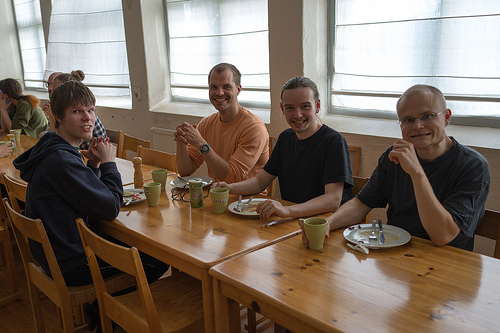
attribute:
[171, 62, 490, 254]
people — sitted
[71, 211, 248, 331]
chair — wooden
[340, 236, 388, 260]
napkin — paper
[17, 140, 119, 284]
jumper — blue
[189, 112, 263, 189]
shirt — orange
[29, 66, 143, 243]
woman — sitted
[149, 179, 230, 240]
shaker — light brown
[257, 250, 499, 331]
wooden table — rectangular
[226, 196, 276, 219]
plate — circular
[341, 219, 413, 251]
plate — white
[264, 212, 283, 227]
knife — silver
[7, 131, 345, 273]
table — rectangular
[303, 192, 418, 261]
plate — circular, white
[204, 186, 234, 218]
cup — brown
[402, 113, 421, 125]
lens — glasses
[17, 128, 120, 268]
jacket — blue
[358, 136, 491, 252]
shirt — dark